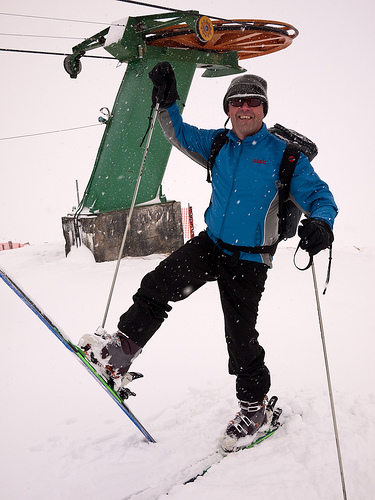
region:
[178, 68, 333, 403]
male skier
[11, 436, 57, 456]
white snow on hill side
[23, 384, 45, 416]
white snow on hill side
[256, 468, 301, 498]
white snow on hill side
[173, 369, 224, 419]
white snow on hill side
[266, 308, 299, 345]
white snow on hill side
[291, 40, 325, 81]
white snow on hill side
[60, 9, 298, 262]
A mountain ski lift.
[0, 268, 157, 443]
The man's right ski.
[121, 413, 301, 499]
The man's left ski.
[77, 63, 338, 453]
A man skiing.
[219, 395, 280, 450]
The man's left ski boot.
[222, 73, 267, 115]
A thermal hat for cold weather.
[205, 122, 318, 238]
The man's backpack.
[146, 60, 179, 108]
The man's right glove.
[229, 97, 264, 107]
Polarized sun glasses.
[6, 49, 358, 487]
this is a man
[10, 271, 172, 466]
blue and green skis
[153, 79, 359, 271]
man wearing a blue jacket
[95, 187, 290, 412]
man wearing black pants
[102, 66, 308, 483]
man standing on now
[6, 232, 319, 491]
man standing on skis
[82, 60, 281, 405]
snow is falling down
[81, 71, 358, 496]
man holding ski poles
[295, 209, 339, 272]
man wearing black gloves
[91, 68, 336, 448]
This man is a skier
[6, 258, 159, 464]
He has one ski up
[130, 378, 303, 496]
This ski is in the snow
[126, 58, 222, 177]
This arm is raised in the air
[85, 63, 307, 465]
This man is skiing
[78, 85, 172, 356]
Ski pole in the air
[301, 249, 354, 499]
Ski pole in the ground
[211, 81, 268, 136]
This man is smiling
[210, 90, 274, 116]
Man is wearing sunglasses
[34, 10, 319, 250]
Ski lift behind skier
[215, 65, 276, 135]
man is wearing sunglasses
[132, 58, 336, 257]
man wearing black gloves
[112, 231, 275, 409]
man's pants are black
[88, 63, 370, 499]
man is holding ski poles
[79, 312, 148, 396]
man's foot off the ground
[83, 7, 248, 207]
greet metal part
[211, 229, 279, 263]
black strap around man's waist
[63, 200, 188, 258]
base of metal part made of concrete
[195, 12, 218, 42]
orange part on metal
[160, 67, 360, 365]
a man is sking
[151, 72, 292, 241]
a man wearing a hat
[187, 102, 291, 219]
a man wearing jacket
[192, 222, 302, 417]
a man wearing pants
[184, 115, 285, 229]
a man wearing blue jacket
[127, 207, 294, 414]
a man wearing black pants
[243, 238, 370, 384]
a man holding a ski pole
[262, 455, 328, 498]
snow on the ground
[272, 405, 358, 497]
white snow on the ground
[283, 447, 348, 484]
ground covered in snow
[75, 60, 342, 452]
tall man on skis